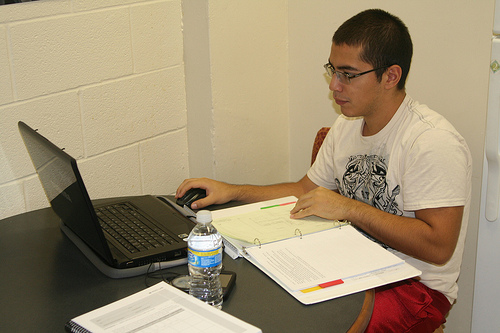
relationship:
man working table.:
[174, 8, 473, 333] [1, 184, 383, 331]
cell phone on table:
[184, 270, 237, 302] [3, 187, 376, 331]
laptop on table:
[17, 120, 225, 269] [2, 190, 420, 331]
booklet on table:
[195, 195, 422, 306] [3, 187, 376, 331]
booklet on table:
[68, 277, 265, 331] [3, 187, 376, 331]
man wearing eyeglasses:
[174, 8, 473, 333] [323, 61, 401, 84]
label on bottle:
[187, 243, 224, 268] [186, 209, 224, 311]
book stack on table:
[65, 288, 268, 331] [0, 178, 402, 331]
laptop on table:
[13, 113, 207, 295] [3, 187, 376, 331]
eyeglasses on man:
[311, 50, 415, 87] [276, 24, 483, 252]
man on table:
[260, 2, 426, 318] [246, 295, 319, 330]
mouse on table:
[176, 188, 206, 208] [3, 187, 376, 331]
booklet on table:
[195, 190, 425, 310] [3, 187, 376, 331]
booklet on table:
[65, 279, 263, 333] [8, 245, 61, 312]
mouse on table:
[176, 182, 211, 206] [2, 190, 420, 331]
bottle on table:
[186, 209, 224, 311] [11, 237, 62, 300]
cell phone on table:
[200, 270, 236, 284] [5, 209, 79, 306]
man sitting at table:
[174, 8, 473, 333] [3, 187, 376, 331]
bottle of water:
[186, 208, 226, 311] [199, 276, 218, 303]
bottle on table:
[186, 208, 226, 311] [3, 187, 376, 331]